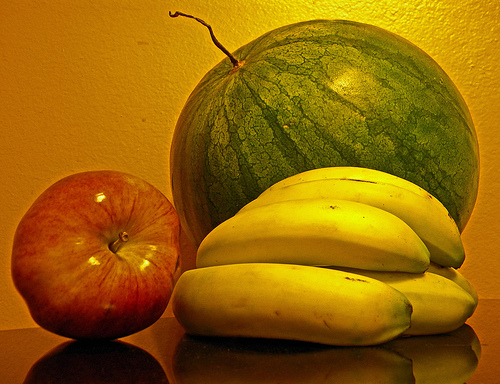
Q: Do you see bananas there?
A: Yes, there is a banana.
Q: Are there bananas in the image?
A: Yes, there is a banana.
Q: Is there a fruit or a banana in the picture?
A: Yes, there is a banana.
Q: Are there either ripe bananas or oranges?
A: Yes, there is a ripe banana.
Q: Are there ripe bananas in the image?
A: Yes, there is a ripe banana.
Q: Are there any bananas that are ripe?
A: Yes, there is a banana that is ripe.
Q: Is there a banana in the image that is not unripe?
A: Yes, there is an ripe banana.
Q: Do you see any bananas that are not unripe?
A: Yes, there is an ripe banana.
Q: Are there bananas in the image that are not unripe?
A: Yes, there is an ripe banana.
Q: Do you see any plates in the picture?
A: No, there are no plates.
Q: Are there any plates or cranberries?
A: No, there are no plates or cranberries.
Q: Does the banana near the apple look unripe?
A: No, the banana is ripe.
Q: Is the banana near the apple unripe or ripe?
A: The banana is ripe.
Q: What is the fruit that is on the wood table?
A: The fruit is a banana.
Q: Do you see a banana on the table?
A: Yes, there is a banana on the table.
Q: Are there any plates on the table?
A: No, there is a banana on the table.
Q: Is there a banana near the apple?
A: Yes, there is a banana near the apple.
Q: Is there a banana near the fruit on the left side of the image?
A: Yes, there is a banana near the apple.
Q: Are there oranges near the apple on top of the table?
A: No, there is a banana near the apple.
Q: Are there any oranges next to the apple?
A: No, there is a banana next to the apple.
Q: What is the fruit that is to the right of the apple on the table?
A: The fruit is a banana.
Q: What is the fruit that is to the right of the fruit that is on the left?
A: The fruit is a banana.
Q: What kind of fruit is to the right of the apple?
A: The fruit is a banana.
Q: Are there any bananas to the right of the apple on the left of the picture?
A: Yes, there is a banana to the right of the apple.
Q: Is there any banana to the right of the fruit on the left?
A: Yes, there is a banana to the right of the apple.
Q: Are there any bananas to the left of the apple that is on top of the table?
A: No, the banana is to the right of the apple.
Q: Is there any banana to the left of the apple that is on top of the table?
A: No, the banana is to the right of the apple.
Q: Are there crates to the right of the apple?
A: No, there is a banana to the right of the apple.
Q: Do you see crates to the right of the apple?
A: No, there is a banana to the right of the apple.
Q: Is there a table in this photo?
A: Yes, there is a table.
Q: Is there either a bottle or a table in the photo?
A: Yes, there is a table.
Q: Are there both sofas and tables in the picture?
A: No, there is a table but no sofas.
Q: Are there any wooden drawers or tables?
A: Yes, there is a wood table.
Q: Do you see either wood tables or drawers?
A: Yes, there is a wood table.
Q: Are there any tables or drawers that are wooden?
A: Yes, the table is wooden.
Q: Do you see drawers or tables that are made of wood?
A: Yes, the table is made of wood.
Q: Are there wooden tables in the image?
A: Yes, there is a wood table.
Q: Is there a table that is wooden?
A: Yes, there is a table that is wooden.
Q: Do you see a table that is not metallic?
A: Yes, there is a wooden table.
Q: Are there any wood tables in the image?
A: Yes, there is a table that is made of wood.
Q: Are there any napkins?
A: No, there are no napkins.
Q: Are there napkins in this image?
A: No, there are no napkins.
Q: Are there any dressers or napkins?
A: No, there are no napkins or dressers.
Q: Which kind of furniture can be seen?
A: The furniture is a table.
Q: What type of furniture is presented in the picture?
A: The furniture is a table.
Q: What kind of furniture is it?
A: The piece of furniture is a table.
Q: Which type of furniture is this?
A: This is a table.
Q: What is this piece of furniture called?
A: This is a table.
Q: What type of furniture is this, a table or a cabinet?
A: This is a table.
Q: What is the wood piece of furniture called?
A: The piece of furniture is a table.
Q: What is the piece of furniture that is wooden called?
A: The piece of furniture is a table.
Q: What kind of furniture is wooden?
A: The furniture is a table.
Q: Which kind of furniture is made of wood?
A: The furniture is a table.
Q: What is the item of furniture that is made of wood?
A: The piece of furniture is a table.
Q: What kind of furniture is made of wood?
A: The furniture is a table.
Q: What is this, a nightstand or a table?
A: This is a table.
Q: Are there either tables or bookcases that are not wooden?
A: No, there is a table but it is wooden.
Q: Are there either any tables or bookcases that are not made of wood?
A: No, there is a table but it is made of wood.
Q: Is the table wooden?
A: Yes, the table is wooden.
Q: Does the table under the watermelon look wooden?
A: Yes, the table is wooden.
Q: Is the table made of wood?
A: Yes, the table is made of wood.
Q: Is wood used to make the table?
A: Yes, the table is made of wood.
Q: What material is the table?
A: The table is made of wood.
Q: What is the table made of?
A: The table is made of wood.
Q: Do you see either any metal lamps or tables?
A: No, there is a table but it is wooden.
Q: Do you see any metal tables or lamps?
A: No, there is a table but it is wooden.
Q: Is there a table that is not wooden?
A: No, there is a table but it is wooden.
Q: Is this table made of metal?
A: No, the table is made of wood.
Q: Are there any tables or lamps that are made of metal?
A: No, there is a table but it is made of wood.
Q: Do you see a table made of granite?
A: No, there is a table but it is made of wood.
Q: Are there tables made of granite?
A: No, there is a table but it is made of wood.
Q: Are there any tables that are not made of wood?
A: No, there is a table but it is made of wood.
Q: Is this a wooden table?
A: Yes, this is a wooden table.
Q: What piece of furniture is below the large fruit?
A: The piece of furniture is a table.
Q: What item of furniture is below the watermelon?
A: The piece of furniture is a table.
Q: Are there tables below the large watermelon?
A: Yes, there is a table below the watermelon.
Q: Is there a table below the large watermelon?
A: Yes, there is a table below the watermelon.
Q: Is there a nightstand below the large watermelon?
A: No, there is a table below the watermelon.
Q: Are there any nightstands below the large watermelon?
A: No, there is a table below the watermelon.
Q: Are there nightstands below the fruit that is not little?
A: No, there is a table below the watermelon.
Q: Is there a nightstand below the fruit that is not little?
A: No, there is a table below the watermelon.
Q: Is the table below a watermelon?
A: Yes, the table is below a watermelon.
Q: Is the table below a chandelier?
A: No, the table is below a watermelon.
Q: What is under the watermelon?
A: The table is under the watermelon.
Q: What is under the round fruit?
A: The table is under the watermelon.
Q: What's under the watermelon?
A: The table is under the watermelon.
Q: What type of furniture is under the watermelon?
A: The piece of furniture is a table.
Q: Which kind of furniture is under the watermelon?
A: The piece of furniture is a table.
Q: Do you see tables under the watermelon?
A: Yes, there is a table under the watermelon.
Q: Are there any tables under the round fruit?
A: Yes, there is a table under the watermelon.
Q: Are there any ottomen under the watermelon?
A: No, there is a table under the watermelon.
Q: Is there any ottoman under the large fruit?
A: No, there is a table under the watermelon.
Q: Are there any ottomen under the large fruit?
A: No, there is a table under the watermelon.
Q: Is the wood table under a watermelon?
A: Yes, the table is under a watermelon.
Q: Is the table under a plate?
A: No, the table is under a watermelon.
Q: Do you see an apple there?
A: Yes, there is an apple.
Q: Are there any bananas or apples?
A: Yes, there is an apple.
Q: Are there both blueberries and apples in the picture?
A: No, there is an apple but no blueberries.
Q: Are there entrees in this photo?
A: No, there are no entrees.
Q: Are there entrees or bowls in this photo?
A: No, there are no entrees or bowls.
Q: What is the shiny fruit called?
A: The fruit is an apple.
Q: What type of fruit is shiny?
A: The fruit is an apple.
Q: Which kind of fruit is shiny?
A: The fruit is an apple.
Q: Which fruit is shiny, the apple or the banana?
A: The apple is shiny.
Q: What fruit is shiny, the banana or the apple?
A: The apple is shiny.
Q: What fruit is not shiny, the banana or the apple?
A: The banana is not shiny.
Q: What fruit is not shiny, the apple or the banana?
A: The banana is not shiny.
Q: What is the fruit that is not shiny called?
A: The fruit is a banana.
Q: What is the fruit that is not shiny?
A: The fruit is a banana.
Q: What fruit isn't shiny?
A: The fruit is a banana.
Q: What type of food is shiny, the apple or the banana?
A: The apple is shiny.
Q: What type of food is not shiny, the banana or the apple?
A: The banana is not shiny.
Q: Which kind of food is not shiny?
A: The food is a banana.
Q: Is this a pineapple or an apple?
A: This is an apple.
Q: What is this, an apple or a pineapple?
A: This is an apple.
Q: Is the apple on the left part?
A: Yes, the apple is on the left of the image.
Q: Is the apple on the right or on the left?
A: The apple is on the left of the image.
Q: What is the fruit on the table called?
A: The fruit is an apple.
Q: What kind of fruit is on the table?
A: The fruit is an apple.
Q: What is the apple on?
A: The apple is on the table.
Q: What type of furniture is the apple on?
A: The apple is on the table.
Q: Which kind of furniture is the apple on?
A: The apple is on the table.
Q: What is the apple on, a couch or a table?
A: The apple is on a table.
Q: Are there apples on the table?
A: Yes, there is an apple on the table.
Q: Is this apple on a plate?
A: No, the apple is on the table.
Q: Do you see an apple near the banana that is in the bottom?
A: Yes, there is an apple near the banana.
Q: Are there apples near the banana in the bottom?
A: Yes, there is an apple near the banana.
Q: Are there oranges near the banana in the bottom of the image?
A: No, there is an apple near the banana.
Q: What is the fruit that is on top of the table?
A: The fruit is an apple.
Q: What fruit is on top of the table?
A: The fruit is an apple.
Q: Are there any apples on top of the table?
A: Yes, there is an apple on top of the table.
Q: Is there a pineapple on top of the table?
A: No, there is an apple on top of the table.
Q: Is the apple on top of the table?
A: Yes, the apple is on top of the table.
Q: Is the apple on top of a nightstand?
A: No, the apple is on top of the table.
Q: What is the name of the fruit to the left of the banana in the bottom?
A: The fruit is an apple.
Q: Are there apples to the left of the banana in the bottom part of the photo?
A: Yes, there is an apple to the left of the banana.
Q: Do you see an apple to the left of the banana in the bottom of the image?
A: Yes, there is an apple to the left of the banana.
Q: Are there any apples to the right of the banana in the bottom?
A: No, the apple is to the left of the banana.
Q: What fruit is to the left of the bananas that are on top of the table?
A: The fruit is an apple.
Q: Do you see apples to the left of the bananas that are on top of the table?
A: Yes, there is an apple to the left of the bananas.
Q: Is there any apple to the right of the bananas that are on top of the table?
A: No, the apple is to the left of the bananas.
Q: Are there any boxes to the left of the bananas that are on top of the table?
A: No, there is an apple to the left of the bananas.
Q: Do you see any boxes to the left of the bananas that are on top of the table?
A: No, there is an apple to the left of the bananas.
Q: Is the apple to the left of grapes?
A: No, the apple is to the left of the bananas.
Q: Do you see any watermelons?
A: Yes, there is a watermelon.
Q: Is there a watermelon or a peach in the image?
A: Yes, there is a watermelon.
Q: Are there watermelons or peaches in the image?
A: Yes, there is a watermelon.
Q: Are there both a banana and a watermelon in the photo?
A: Yes, there are both a watermelon and a banana.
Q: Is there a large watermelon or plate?
A: Yes, there is a large watermelon.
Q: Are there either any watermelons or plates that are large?
A: Yes, the watermelon is large.